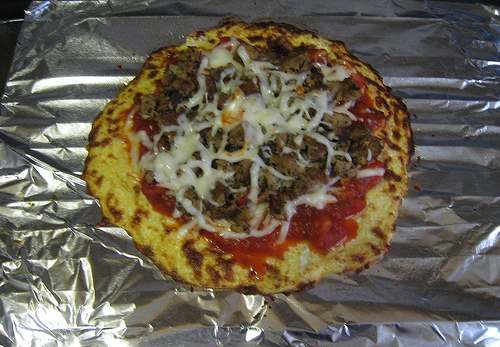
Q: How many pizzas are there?
A: One.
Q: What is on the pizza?
A: Meat and cheese.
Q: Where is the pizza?
A: On tin foil.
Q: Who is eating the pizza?
A: No one.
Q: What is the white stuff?
A: Cheese.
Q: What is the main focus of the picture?
A: A pizza.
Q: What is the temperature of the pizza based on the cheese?
A: Warm or hot.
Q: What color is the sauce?
A: Red.